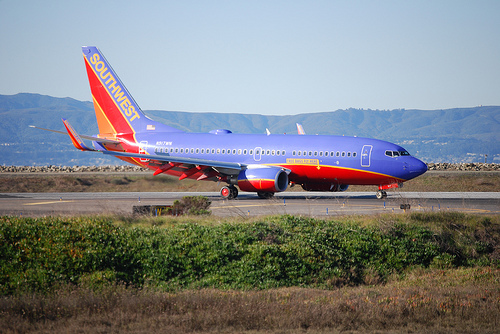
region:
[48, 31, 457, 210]
a big multicolored plane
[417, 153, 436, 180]
the nose of the plane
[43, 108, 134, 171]
part of the tail of the plane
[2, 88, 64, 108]
the top of the mountain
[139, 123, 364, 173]
a row of windows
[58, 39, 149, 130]
the top of the tail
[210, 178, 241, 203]
the wheel of the plane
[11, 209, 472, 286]
some greens bushes in the fron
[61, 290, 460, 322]
some dead grass in the front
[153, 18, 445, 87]
a smoggy sky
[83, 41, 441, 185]
a blue and red plane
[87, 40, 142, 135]
tail of plane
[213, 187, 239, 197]
wheels of plane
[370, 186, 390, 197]
front wheels of plane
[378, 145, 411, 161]
window on plane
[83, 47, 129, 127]
name on airplane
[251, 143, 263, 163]
door on airplane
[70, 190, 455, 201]
runway under airplane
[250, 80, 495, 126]
hills behind plane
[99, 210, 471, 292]
bushes in front of plane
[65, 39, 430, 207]
large blue airplane on the ground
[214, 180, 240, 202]
black and red wheels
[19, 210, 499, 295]
long green bushes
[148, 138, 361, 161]
row of windows on an airplane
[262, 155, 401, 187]
red paint on blue airplane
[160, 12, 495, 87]
clear blue cloudless sky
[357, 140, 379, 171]
door of an airplane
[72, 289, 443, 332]
dried brown grass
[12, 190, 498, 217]
black concrete road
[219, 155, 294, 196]
engine of an airplane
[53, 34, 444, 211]
a plane on a landing lane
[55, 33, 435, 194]
plane is blue, red and orange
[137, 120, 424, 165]
top part of the plane is blue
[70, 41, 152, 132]
vertical stabilizer is blue, red and orange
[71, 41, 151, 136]
vertical stabilizer has yellow stripes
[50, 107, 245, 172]
wing of plane is blue and red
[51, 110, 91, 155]
tip of the wing is red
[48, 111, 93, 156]
tip of the wing is bend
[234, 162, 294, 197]
engine of plane is blue and red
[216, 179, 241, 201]
back wheel of plane is black and red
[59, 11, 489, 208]
a plane on the ground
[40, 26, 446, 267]
an airplane on the ground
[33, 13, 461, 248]
a plane on the runway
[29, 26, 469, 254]
an airplane on the runway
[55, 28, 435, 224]
a blue and red plane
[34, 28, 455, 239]
a passenger plane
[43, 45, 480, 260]
a passenger airplane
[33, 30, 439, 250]
a blue train on a runway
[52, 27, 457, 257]
a blue airplane on the runway